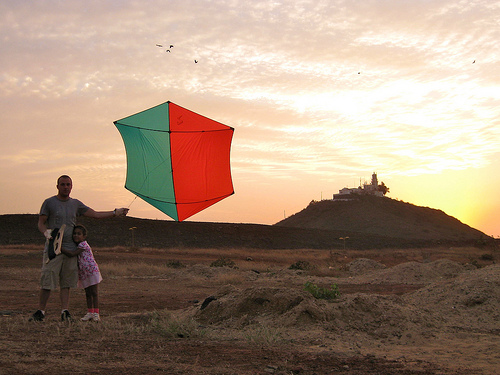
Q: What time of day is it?
A: Dusk.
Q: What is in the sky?
A: Clouds.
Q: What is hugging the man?
A: Girl.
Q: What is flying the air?
A: Birds.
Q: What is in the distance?
A: Hilltop.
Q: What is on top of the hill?
A: House.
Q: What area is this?
A: Field.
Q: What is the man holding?
A: A kite.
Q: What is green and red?
A: A kite.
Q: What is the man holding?
A: A red and green kite.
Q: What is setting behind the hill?
A: The sun.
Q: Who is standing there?
A: A man and child.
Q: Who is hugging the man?
A: A child.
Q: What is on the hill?
A: A house.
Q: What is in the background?
A: A house on the hill.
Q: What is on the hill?
A: A house.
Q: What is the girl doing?
A: Hugging the man.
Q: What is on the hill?
A: A large building.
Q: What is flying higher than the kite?
A: Birds.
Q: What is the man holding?
A: Kite.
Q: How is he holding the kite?
A: String.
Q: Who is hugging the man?
A: Child.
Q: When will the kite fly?
A: When it is windy.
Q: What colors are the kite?
A: Red and green.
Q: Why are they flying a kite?
A: Recreation.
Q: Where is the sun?
A: Behind a hill.